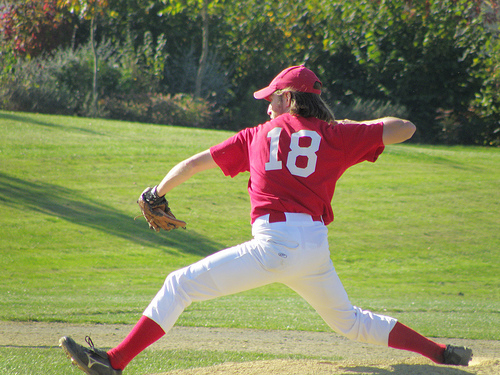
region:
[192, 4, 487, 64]
green leaves on trees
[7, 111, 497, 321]
green grass on hill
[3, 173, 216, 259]
shadow on green grass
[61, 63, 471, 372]
player in pitching stance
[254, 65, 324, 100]
red hat on head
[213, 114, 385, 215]
red shirt of uniform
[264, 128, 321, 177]
white number on red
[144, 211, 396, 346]
white pants of uniform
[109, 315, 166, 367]
red stock on leg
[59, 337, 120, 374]
shoe with cleats on bottom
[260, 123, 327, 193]
number 18 on a jersey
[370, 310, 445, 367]
man wearing red socks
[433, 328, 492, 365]
man wearing black cleats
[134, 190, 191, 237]
man wearing a baseball glove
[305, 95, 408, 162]
man throwing a pitch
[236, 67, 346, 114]
man wearing a red baseball hat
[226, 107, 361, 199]
man wearing a red tee shirt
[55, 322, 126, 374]
person wearing black sneakers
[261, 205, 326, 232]
person wear a red belt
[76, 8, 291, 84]
leaves on the tree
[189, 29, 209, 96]
trunk of the tree.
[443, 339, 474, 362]
shoe on player's foot.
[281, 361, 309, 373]
dirt on the mound.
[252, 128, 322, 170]
number on the jersey.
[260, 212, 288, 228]
belt on player's waist.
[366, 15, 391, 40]
leaves on the tree.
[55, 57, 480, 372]
A baseball pitcher ready to throw a ball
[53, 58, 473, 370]
A baseball pitcher ready to throw a ball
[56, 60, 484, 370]
A baseball pitcher ready to throw a ball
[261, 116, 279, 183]
White number on a red shirt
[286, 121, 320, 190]
White number on a red shirt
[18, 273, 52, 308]
PAtch of bright green grass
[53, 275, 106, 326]
PAtch of bright green grass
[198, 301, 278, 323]
PAtch of bright green grass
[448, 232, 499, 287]
PAtch of bright green grass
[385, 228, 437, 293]
PAtch of bright green grass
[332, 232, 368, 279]
PAtch of bright green grass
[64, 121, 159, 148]
PAtch of bright green grass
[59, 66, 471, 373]
A baseball player in action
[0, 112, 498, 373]
The green baseball grounds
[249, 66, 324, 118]
The baseball player wearing a hat.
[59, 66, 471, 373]
The baseball player in white and red uniform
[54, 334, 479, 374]
The dark playing snickers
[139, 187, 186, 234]
The brown baseball glove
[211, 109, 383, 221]
The t-shirt labelled eighteen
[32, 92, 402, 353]
this is a baseball player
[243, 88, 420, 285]
the man is throwing a baseball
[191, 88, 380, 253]
the jersey is red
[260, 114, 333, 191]
the number is white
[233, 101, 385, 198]
the number is 18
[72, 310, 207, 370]
the socks are red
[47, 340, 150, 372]
these are baseball cleats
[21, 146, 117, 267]
the lawn is mowed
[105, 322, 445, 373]
Red tube socks.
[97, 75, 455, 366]
A baseball player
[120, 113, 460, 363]
A red and white baseball uniform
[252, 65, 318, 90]
A red baseball cap.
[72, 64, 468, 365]
A person with brown long hair.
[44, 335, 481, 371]
Black cleats.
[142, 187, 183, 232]
A black and brown baseball glove.